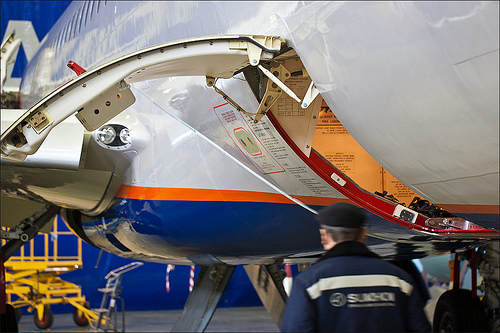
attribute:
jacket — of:
[287, 251, 430, 331]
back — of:
[318, 273, 395, 327]